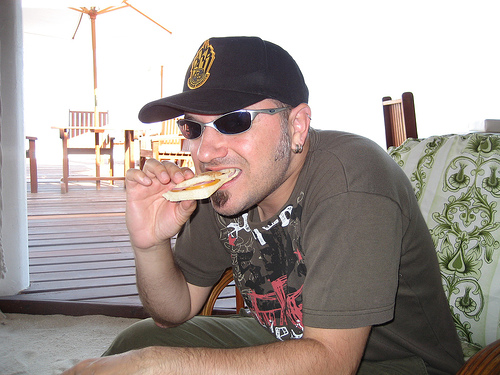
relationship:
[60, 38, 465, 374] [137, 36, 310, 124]
man wearing a cap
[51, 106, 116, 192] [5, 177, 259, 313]
chair on deck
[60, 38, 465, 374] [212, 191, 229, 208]
man has a soul patch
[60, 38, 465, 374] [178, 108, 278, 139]
man wearing sunglasses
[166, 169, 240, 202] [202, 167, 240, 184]
pizza in mans mouth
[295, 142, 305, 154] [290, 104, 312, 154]
earring in mans ear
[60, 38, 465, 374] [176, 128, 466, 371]
man wearing brown shirt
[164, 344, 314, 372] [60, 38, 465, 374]
arm hair of man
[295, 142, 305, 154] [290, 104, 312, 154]
earring on mans ear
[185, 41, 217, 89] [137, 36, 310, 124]
logo on cap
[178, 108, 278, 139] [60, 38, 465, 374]
sunglasses on man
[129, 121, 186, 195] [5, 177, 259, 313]
bench on deck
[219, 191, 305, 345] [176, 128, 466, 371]
logo on shirt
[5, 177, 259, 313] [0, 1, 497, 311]
deck in background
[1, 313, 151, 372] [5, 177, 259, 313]
sand by deck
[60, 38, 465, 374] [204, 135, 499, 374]
man sitting on a chair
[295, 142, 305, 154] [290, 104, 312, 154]
earring in an ear